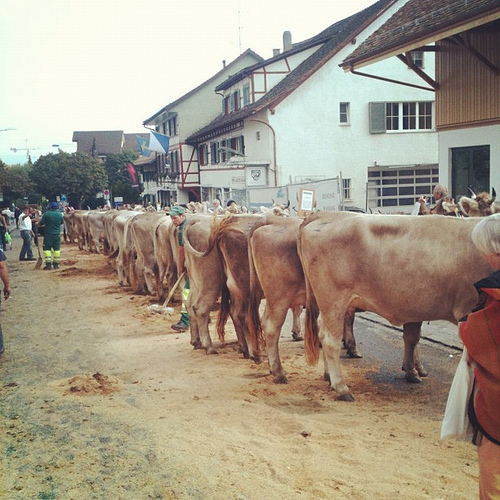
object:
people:
[17, 204, 35, 263]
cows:
[244, 222, 306, 389]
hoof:
[336, 392, 355, 401]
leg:
[313, 294, 351, 402]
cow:
[297, 211, 495, 404]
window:
[339, 103, 347, 124]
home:
[186, 3, 437, 211]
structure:
[247, 170, 344, 218]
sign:
[300, 190, 314, 211]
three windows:
[384, 101, 433, 131]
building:
[337, 1, 499, 208]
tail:
[297, 217, 322, 365]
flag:
[148, 130, 169, 155]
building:
[143, 48, 268, 212]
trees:
[29, 150, 106, 212]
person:
[420, 184, 449, 215]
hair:
[433, 185, 446, 197]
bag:
[411, 201, 421, 215]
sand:
[1, 236, 480, 498]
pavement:
[1, 229, 482, 498]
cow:
[180, 214, 235, 354]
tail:
[183, 216, 233, 259]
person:
[37, 202, 65, 271]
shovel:
[34, 223, 43, 271]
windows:
[242, 87, 249, 104]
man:
[18, 206, 35, 261]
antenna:
[236, 3, 243, 55]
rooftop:
[142, 48, 266, 124]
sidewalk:
[357, 311, 464, 351]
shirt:
[40, 209, 64, 234]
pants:
[43, 234, 61, 264]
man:
[167, 206, 192, 332]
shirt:
[18, 213, 33, 231]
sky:
[1, 1, 375, 159]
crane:
[9, 138, 59, 163]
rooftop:
[187, 1, 399, 144]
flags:
[137, 136, 152, 156]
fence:
[201, 174, 342, 208]